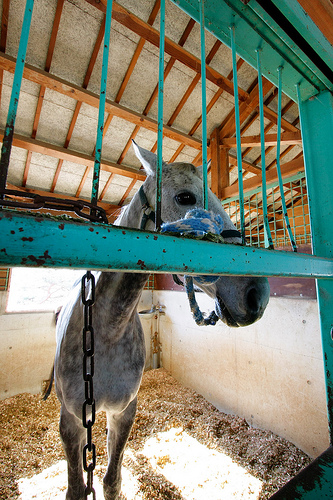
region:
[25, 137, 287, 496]
THIS IS A BIG HORSE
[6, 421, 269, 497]
THE LIGHT IS ON THE GROUND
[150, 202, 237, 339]
THE HORSE IS TIED UP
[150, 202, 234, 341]
THE ROPE IS BLUE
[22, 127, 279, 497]
THE HORSE IS GREY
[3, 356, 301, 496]
THE FLOOR IS COVERED IN SAWDUST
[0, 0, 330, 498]
THE BARS ARE GREEN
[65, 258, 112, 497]
THE CHAIN IS ON THE BARS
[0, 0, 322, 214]
THE CEILING HAS WOODEN RAFTERS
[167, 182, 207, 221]
THE HORSE HAS AN EYE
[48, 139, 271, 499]
horse stands in stall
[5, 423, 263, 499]
light from window shines into stall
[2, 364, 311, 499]
bedding covers the floor of the stall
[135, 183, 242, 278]
halter is worn on horse's head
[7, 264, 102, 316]
window lets light into the stall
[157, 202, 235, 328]
rope stops horse from moving around too much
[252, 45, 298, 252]
bars are dented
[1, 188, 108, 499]
chain hangs down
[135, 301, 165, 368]
water fountain for horse to drink from sits in the corner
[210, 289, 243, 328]
horse's mouth is closed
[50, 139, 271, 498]
malnourished horse is tied to bars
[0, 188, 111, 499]
large chain wove in fence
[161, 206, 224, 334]
horse is tied to bars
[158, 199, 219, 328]
blue and white rope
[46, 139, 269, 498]
horse is white and brown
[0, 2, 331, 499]
metal bars are painted aqua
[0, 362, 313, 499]
horse is standing in wood chips and hay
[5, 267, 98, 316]
window with light is pearing in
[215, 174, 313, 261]
metal bars on side wall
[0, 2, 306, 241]
rafters in ceiling are wooden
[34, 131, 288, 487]
a horse in a stall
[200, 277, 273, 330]
the nose on a horse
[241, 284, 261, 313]
the nostril on a horse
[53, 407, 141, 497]
the front legs on a horse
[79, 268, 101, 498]
a chain in a horse stall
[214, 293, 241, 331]
the mouth on a horse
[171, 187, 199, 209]
the eye on a horse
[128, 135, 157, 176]
the ear on a horse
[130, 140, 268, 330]
the head on a horse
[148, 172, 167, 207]
part of a metal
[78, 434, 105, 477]
part of a chain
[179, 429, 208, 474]
part of a floor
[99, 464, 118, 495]
part of a chain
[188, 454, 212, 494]
part of a floor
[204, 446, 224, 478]
part of a floor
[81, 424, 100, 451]
part of a chain